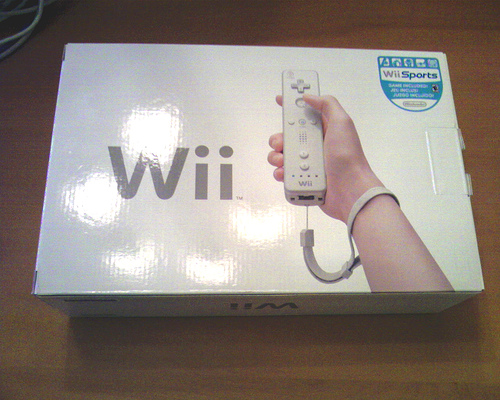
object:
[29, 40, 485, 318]
box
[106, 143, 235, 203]
wii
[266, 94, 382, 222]
hand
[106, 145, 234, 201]
symbol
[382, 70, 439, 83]
wii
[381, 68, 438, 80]
symbol.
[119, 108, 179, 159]
glare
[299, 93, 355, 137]
thumb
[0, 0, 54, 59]
corner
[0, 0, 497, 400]
picture.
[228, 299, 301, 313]
symbol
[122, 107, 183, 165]
reflecting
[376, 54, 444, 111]
blue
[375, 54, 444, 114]
label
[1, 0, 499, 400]
table.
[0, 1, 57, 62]
top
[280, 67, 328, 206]
controller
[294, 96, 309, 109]
circle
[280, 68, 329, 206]
wii.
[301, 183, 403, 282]
strap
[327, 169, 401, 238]
wrist.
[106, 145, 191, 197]
letters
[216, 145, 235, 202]
letter.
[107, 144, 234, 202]
game.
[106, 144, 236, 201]
logo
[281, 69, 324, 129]
top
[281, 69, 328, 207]
white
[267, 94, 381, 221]
holding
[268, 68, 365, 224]
image.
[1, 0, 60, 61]
cables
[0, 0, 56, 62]
background.